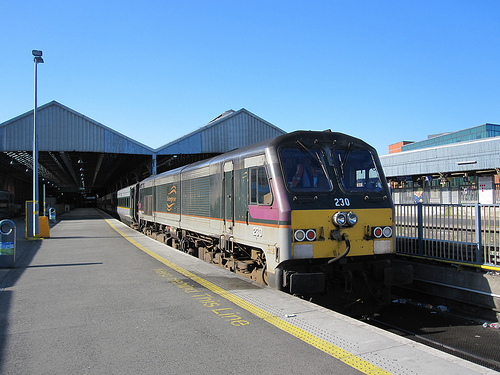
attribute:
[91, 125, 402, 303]
train — silver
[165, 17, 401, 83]
sky — blue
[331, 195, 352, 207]
number — 320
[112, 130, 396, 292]
train — yellow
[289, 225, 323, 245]
headlights — off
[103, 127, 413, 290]
train — yellow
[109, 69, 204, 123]
clouds — white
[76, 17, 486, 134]
sky — blue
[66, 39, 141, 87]
clouds — white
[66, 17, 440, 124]
sky — blue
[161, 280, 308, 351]
words — yellow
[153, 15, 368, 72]
sky — blue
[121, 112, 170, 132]
cloud — white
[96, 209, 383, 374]
line — yellow, caution line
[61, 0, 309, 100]
clouds — white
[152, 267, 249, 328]
writing — yellow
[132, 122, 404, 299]
train engine — grey, black, yellow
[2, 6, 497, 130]
sky — blue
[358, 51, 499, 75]
sky — clear, blue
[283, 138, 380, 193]
wipers — windshield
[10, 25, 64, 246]
light post — metal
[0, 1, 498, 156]
sky — blue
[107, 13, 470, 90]
sky — blue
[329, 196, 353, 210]
number — train's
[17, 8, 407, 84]
clouds — white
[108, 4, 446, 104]
clouds — white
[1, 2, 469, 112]
sky — blue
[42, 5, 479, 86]
clouds — white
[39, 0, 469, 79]
clouds — white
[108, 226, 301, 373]
line — yellow